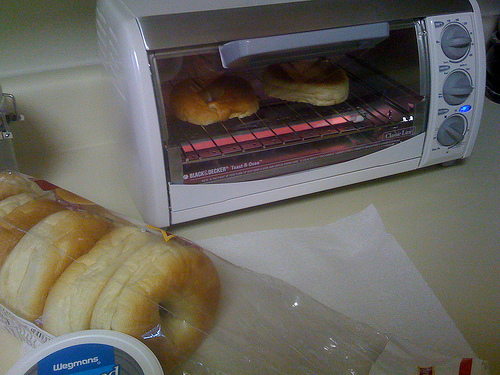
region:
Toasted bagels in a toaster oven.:
[169, 73, 374, 118]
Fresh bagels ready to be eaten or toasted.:
[4, 172, 230, 373]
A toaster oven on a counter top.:
[93, 2, 479, 222]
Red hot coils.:
[163, 115, 436, 158]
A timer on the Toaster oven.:
[442, 20, 470, 62]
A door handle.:
[198, 18, 395, 66]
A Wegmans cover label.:
[23, 345, 170, 373]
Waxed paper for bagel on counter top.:
[295, 210, 487, 309]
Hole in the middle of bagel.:
[156, 295, 181, 329]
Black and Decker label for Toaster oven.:
[184, 163, 269, 182]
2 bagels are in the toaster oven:
[128, 61, 493, 191]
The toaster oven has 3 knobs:
[427, 22, 499, 196]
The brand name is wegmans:
[14, 305, 226, 373]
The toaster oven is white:
[78, 3, 466, 204]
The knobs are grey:
[413, 33, 486, 195]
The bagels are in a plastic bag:
[3, 175, 221, 354]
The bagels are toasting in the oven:
[170, 0, 375, 207]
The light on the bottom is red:
[166, 85, 488, 202]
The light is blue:
[444, 93, 480, 125]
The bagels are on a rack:
[144, 59, 486, 199]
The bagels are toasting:
[153, 57, 393, 170]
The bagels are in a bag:
[25, 201, 265, 360]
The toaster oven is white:
[122, 8, 273, 218]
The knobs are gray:
[439, 22, 494, 170]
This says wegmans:
[43, 356, 113, 374]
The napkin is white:
[275, 239, 489, 344]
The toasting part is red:
[187, 130, 411, 179]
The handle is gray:
[193, 14, 420, 71]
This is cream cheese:
[20, 325, 135, 374]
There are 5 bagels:
[2, 174, 285, 374]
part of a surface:
[425, 194, 467, 236]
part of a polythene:
[251, 307, 307, 342]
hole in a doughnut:
[165, 307, 186, 326]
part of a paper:
[369, 252, 403, 284]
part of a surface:
[430, 232, 453, 254]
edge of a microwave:
[178, 212, 225, 237]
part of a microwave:
[166, 157, 215, 206]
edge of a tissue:
[403, 252, 432, 297]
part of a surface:
[443, 235, 488, 278]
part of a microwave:
[286, 55, 351, 107]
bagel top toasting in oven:
[170, 71, 262, 126]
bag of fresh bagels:
[0, 182, 219, 360]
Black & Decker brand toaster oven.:
[88, 0, 488, 225]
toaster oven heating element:
[174, 110, 382, 160]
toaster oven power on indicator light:
[456, 101, 473, 117]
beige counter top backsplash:
[26, 69, 98, 152]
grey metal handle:
[210, 5, 400, 85]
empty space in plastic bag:
[230, 307, 497, 369]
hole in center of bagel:
[155, 298, 172, 323]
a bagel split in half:
[168, 52, 357, 124]